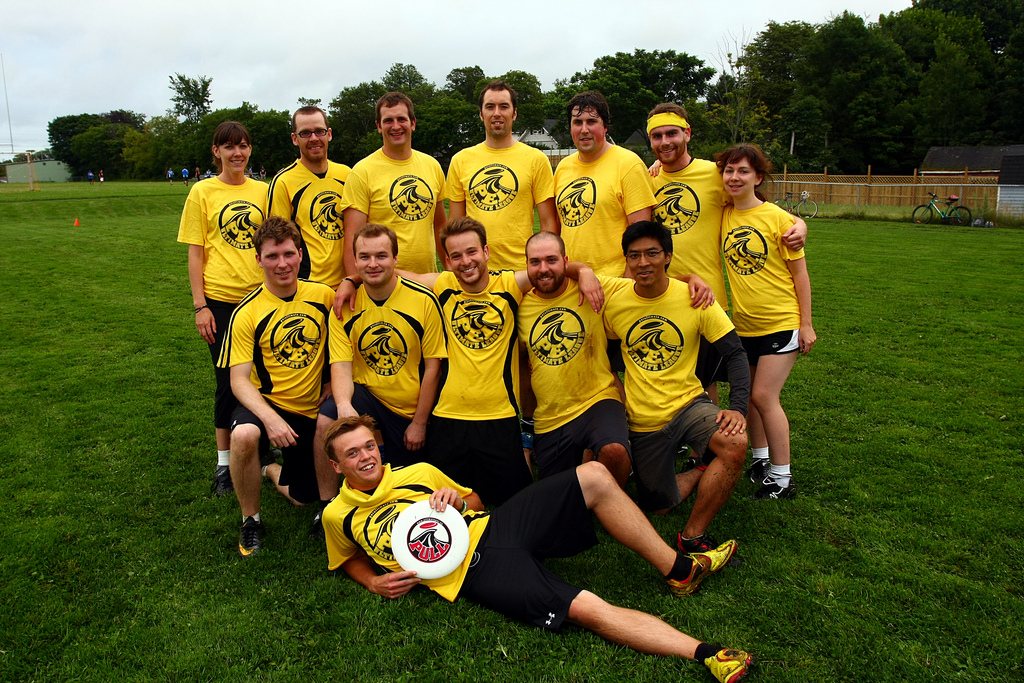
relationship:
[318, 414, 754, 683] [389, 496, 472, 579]
boy holding frisbee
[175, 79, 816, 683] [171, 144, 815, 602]
group wearing uniforms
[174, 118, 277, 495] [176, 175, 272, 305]
woman wearing shirt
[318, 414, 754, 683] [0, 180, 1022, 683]
boy on field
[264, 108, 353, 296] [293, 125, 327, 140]
man wearing glasses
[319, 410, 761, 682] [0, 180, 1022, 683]
boy on field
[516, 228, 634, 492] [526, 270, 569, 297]
man has a beard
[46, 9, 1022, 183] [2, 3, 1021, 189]
trees are in background